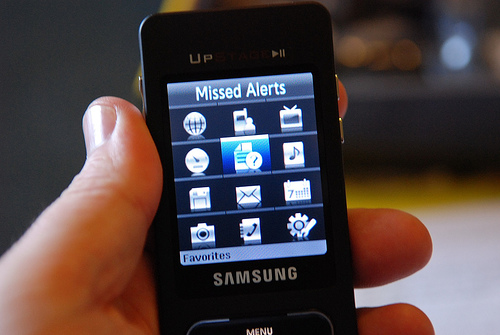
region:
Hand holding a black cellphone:
[1, 0, 436, 334]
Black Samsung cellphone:
[135, 0, 361, 333]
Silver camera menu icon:
[186, 220, 218, 246]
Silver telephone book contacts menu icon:
[235, 214, 263, 245]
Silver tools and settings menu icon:
[282, 210, 317, 241]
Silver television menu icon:
[276, 102, 303, 132]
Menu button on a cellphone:
[227, 312, 289, 334]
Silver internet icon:
[181, 110, 208, 135]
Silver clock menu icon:
[182, 146, 212, 176]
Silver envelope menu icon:
[230, 182, 265, 210]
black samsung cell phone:
[138, 1, 360, 331]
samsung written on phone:
[210, 261, 310, 286]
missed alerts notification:
[195, 80, 285, 101]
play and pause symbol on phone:
[273, 42, 288, 61]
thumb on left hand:
[70, 95, 155, 190]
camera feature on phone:
[186, 220, 218, 245]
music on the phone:
[280, 135, 310, 170]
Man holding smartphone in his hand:
[4, 1, 436, 333]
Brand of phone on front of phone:
[211, 265, 298, 287]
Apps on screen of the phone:
[180, 104, 320, 249]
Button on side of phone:
[338, 117, 345, 142]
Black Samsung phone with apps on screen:
[138, 1, 360, 333]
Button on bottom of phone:
[237, 323, 276, 333]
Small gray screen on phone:
[155, 70, 329, 267]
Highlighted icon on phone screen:
[218, 133, 273, 175]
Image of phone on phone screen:
[246, 220, 256, 238]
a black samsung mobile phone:
[134, 4, 359, 334]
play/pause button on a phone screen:
[264, 44, 290, 62]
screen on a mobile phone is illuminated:
[163, 69, 331, 269]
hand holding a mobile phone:
[5, 9, 445, 334]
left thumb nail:
[75, 95, 120, 154]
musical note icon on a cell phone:
[281, 141, 311, 169]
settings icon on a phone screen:
[285, 208, 316, 243]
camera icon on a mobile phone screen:
[186, 218, 221, 249]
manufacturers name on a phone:
[208, 263, 300, 288]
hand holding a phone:
[65, 14, 439, 334]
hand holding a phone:
[50, 18, 417, 333]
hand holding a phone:
[47, 10, 436, 322]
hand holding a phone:
[85, 42, 402, 334]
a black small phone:
[136, 8, 378, 333]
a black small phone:
[119, 12, 364, 331]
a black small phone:
[110, 23, 366, 333]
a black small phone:
[119, 17, 356, 326]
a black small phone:
[131, 8, 356, 334]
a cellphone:
[145, 18, 355, 330]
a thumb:
[78, 103, 124, 146]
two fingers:
[358, 209, 422, 331]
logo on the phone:
[209, 260, 301, 285]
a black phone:
[141, 9, 358, 320]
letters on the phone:
[241, 321, 273, 333]